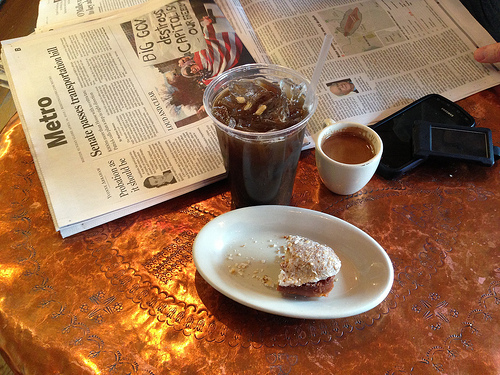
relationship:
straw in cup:
[302, 33, 335, 112] [204, 63, 316, 210]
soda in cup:
[214, 75, 304, 208] [204, 63, 316, 210]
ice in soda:
[211, 75, 308, 132] [214, 75, 304, 208]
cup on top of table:
[204, 63, 316, 210] [3, 4, 499, 374]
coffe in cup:
[321, 132, 378, 164] [315, 116, 384, 195]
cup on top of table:
[315, 116, 384, 195] [3, 4, 499, 374]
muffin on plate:
[277, 234, 341, 298] [194, 204, 394, 321]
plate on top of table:
[194, 204, 394, 321] [3, 4, 499, 374]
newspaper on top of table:
[4, 1, 499, 240] [3, 4, 499, 374]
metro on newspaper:
[37, 97, 69, 149] [4, 1, 499, 240]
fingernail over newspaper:
[473, 43, 500, 65] [4, 1, 499, 240]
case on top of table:
[411, 119, 498, 168] [3, 4, 499, 374]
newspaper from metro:
[4, 1, 499, 240] [37, 97, 69, 149]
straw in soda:
[302, 33, 335, 112] [214, 75, 304, 208]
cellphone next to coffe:
[367, 92, 476, 180] [321, 132, 378, 164]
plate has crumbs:
[194, 204, 394, 321] [229, 232, 291, 292]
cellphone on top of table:
[367, 92, 476, 180] [3, 4, 499, 374]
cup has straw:
[204, 63, 316, 210] [302, 33, 335, 112]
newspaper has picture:
[4, 1, 499, 240] [113, 1, 264, 129]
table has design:
[3, 4, 499, 374] [8, 153, 500, 373]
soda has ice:
[214, 75, 304, 208] [211, 75, 308, 132]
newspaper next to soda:
[4, 1, 499, 240] [214, 75, 304, 208]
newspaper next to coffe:
[4, 1, 499, 240] [321, 132, 378, 164]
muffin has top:
[277, 234, 341, 298] [278, 235, 341, 286]